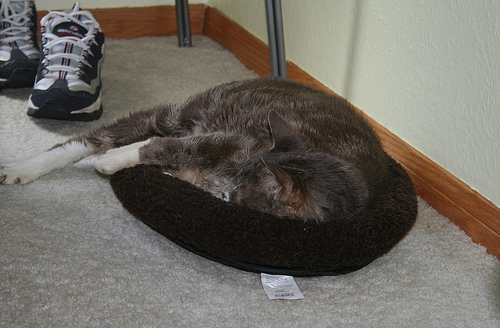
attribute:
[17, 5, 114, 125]
sneaker — blue, white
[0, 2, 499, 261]
trim — wooden, brown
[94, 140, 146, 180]
paw — white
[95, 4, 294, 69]
base — wooden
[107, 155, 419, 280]
pet bed — black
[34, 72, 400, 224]
cat — white, grey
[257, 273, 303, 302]
tag — white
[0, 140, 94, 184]
paw — white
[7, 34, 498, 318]
carpet — white, tan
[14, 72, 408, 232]
cat — white, brown, sleeping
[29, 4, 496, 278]
base board — wooden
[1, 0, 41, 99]
sneaker — blue, white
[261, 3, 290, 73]
leg — silver, metal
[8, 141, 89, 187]
paw — white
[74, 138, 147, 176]
paw — white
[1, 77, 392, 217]
cat — lying down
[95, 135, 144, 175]
foot — white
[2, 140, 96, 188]
foot — white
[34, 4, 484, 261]
baseboard — wooden, wood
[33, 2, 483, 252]
moulding — wooden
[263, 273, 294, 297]
text — black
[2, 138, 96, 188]
paw — white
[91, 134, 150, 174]
paw — white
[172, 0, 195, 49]
chair leg — metal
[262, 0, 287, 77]
chair leg — metal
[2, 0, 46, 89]
sneaker — black, white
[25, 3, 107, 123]
sneaker — black, white